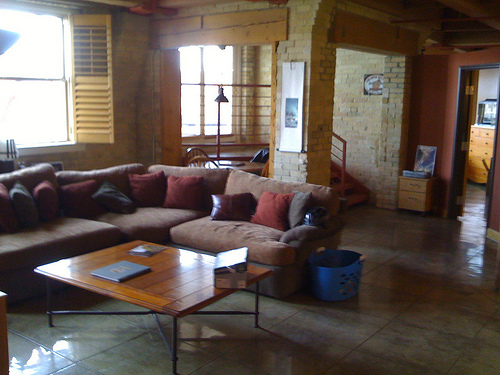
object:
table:
[33, 236, 276, 372]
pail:
[311, 245, 365, 302]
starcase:
[185, 81, 374, 211]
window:
[0, 5, 74, 150]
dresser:
[397, 168, 435, 212]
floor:
[1, 182, 499, 374]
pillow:
[209, 186, 256, 223]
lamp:
[215, 86, 229, 170]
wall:
[0, 3, 412, 211]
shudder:
[69, 12, 113, 145]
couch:
[0, 160, 342, 306]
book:
[90, 257, 153, 284]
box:
[215, 242, 252, 293]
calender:
[279, 60, 307, 153]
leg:
[44, 273, 57, 328]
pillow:
[95, 180, 140, 213]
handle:
[314, 246, 326, 254]